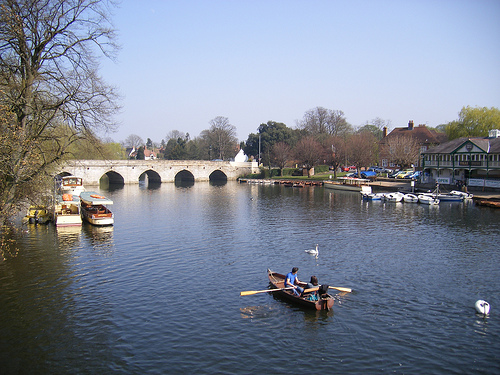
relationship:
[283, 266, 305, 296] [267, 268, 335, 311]
man are in boat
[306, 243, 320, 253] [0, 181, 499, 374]
bird in water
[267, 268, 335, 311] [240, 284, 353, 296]
boat has two paddles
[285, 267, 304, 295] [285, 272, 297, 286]
man wearing a blue shirt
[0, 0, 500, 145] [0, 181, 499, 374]
sky above water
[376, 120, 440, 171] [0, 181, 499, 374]
house near water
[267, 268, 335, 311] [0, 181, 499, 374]
boat in water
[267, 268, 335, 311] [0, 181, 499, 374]
boat near water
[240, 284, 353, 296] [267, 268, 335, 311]
two paddles are near boat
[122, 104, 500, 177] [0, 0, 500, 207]
trees are in distance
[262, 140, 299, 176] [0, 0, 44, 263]
trees has leaves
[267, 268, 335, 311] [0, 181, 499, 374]
boat on water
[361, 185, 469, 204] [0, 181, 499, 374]
boats are on water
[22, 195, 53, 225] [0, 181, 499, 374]
boat on water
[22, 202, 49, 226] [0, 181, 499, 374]
boat are on water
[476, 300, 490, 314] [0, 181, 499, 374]
buoy on water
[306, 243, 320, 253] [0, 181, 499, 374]
bird on water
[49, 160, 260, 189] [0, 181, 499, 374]
bridge over water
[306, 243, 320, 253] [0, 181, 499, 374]
swan on water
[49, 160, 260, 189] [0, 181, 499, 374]
bridge on water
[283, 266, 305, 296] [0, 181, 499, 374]
man are on water